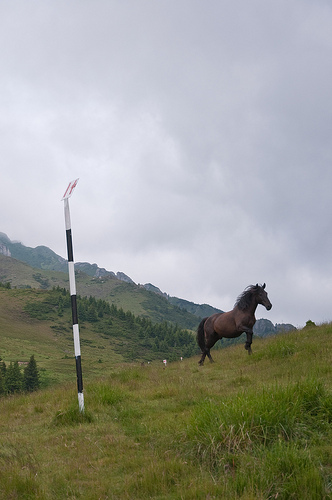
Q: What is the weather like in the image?
A: It is cloudy.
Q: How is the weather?
A: It is cloudy.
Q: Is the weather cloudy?
A: Yes, it is cloudy.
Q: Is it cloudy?
A: Yes, it is cloudy.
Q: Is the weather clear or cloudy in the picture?
A: It is cloudy.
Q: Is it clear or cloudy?
A: It is cloudy.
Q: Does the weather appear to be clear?
A: No, it is cloudy.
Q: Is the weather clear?
A: No, it is cloudy.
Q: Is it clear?
A: No, it is cloudy.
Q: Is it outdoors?
A: Yes, it is outdoors.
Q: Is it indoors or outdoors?
A: It is outdoors.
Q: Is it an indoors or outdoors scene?
A: It is outdoors.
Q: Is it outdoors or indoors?
A: It is outdoors.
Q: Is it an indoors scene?
A: No, it is outdoors.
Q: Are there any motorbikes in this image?
A: No, there are no motorbikes.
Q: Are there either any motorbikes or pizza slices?
A: No, there are no motorbikes or pizza slices.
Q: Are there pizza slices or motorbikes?
A: No, there are no motorbikes or pizza slices.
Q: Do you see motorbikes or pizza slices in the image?
A: No, there are no motorbikes or pizza slices.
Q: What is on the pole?
A: The marker is on the pole.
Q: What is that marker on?
A: The marker is on the pole.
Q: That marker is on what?
A: The marker is on the pole.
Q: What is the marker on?
A: The marker is on the pole.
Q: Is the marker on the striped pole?
A: Yes, the marker is on the pole.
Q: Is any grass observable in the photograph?
A: Yes, there is grass.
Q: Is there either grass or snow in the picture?
A: Yes, there is grass.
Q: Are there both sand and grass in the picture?
A: No, there is grass but no sand.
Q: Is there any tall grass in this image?
A: Yes, there is tall grass.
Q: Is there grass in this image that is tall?
A: Yes, there is grass that is tall.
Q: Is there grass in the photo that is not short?
A: Yes, there is tall grass.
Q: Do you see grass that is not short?
A: Yes, there is tall grass.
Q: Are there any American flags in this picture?
A: No, there are no American flags.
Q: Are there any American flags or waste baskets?
A: No, there are no American flags or waste baskets.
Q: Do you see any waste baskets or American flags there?
A: No, there are no American flags or waste baskets.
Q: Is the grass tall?
A: Yes, the grass is tall.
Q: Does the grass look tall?
A: Yes, the grass is tall.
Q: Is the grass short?
A: No, the grass is tall.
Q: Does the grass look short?
A: No, the grass is tall.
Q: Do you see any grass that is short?
A: No, there is grass but it is tall.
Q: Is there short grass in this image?
A: No, there is grass but it is tall.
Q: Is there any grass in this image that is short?
A: No, there is grass but it is tall.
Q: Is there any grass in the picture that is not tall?
A: No, there is grass but it is tall.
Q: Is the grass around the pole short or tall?
A: The grass is tall.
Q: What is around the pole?
A: The grass is around the pole.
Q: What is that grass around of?
A: The grass is around the pole.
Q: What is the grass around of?
A: The grass is around the pole.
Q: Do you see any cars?
A: No, there are no cars.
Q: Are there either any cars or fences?
A: No, there are no cars or fences.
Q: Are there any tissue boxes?
A: No, there are no tissue boxes.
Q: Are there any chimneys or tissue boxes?
A: No, there are no tissue boxes or chimneys.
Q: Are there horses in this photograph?
A: Yes, there is a horse.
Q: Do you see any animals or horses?
A: Yes, there is a horse.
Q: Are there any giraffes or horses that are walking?
A: Yes, the horse is walking.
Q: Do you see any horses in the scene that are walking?
A: Yes, there is a horse that is walking.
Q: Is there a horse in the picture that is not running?
A: Yes, there is a horse that is walking.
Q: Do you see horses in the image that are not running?
A: Yes, there is a horse that is walking .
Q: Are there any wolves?
A: No, there are no wolves.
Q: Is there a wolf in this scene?
A: No, there are no wolves.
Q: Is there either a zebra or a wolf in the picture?
A: No, there are no wolves or zebras.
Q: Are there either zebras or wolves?
A: No, there are no wolves or zebras.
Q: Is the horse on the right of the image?
A: Yes, the horse is on the right of the image.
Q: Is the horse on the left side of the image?
A: No, the horse is on the right of the image.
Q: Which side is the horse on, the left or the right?
A: The horse is on the right of the image.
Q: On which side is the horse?
A: The horse is on the right of the image.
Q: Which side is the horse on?
A: The horse is on the right of the image.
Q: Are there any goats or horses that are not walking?
A: No, there is a horse but it is walking.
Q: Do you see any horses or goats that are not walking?
A: No, there is a horse but it is walking.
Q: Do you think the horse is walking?
A: Yes, the horse is walking.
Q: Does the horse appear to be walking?
A: Yes, the horse is walking.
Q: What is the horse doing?
A: The horse is walking.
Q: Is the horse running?
A: No, the horse is walking.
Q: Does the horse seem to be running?
A: No, the horse is walking.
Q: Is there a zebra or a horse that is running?
A: No, there is a horse but it is walking.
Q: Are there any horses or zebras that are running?
A: No, there is a horse but it is walking.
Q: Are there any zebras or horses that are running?
A: No, there is a horse but it is walking.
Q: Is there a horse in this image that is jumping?
A: No, there is a horse but it is walking.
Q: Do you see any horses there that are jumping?
A: No, there is a horse but it is walking.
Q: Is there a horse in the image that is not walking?
A: No, there is a horse but it is walking.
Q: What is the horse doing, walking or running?
A: The horse is walking.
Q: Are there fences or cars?
A: No, there are no cars or fences.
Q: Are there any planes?
A: No, there are no planes.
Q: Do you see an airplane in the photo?
A: No, there are no airplanes.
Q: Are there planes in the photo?
A: No, there are no planes.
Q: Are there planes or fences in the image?
A: No, there are no planes or fences.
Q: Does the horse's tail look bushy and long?
A: Yes, the tail is bushy and long.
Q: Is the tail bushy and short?
A: No, the tail is bushy but long.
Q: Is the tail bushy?
A: Yes, the tail is bushy.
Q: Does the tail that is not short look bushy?
A: Yes, the tail is bushy.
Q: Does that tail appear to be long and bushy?
A: Yes, the tail is long and bushy.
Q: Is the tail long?
A: Yes, the tail is long.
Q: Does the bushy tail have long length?
A: Yes, the tail is long.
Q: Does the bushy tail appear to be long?
A: Yes, the tail is long.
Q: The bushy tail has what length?
A: The tail is long.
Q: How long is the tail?
A: The tail is long.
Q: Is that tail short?
A: No, the tail is long.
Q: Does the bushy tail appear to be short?
A: No, the tail is long.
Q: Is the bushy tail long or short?
A: The tail is long.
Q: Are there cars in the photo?
A: No, there are no cars.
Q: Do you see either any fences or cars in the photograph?
A: No, there are no cars or fences.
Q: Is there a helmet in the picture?
A: No, there are no helmets.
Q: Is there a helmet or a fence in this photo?
A: No, there are no helmets or fences.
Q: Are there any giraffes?
A: No, there are no giraffes.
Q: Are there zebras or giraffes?
A: No, there are no giraffes or zebras.